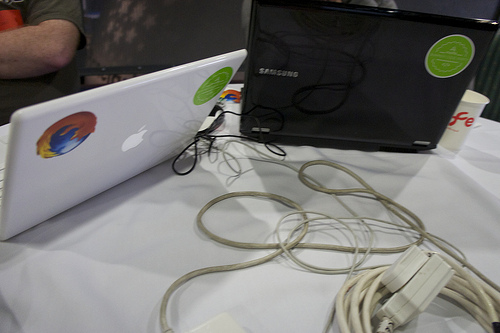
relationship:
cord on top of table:
[357, 244, 455, 328] [104, 229, 161, 258]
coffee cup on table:
[451, 77, 482, 162] [104, 229, 161, 258]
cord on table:
[357, 244, 455, 328] [104, 229, 161, 258]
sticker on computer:
[410, 35, 470, 87] [258, 12, 432, 148]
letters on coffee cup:
[456, 112, 476, 126] [451, 77, 482, 162]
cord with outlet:
[357, 244, 455, 328] [375, 312, 395, 331]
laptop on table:
[14, 68, 197, 218] [104, 229, 161, 258]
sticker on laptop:
[410, 35, 470, 87] [14, 68, 197, 218]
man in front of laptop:
[6, 7, 104, 83] [14, 68, 197, 218]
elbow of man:
[47, 47, 80, 72] [6, 7, 104, 83]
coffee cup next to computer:
[451, 77, 482, 162] [258, 12, 432, 148]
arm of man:
[1, 19, 76, 81] [6, 7, 104, 83]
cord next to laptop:
[357, 244, 455, 328] [14, 68, 197, 218]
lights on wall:
[86, 6, 159, 48] [186, 21, 232, 52]